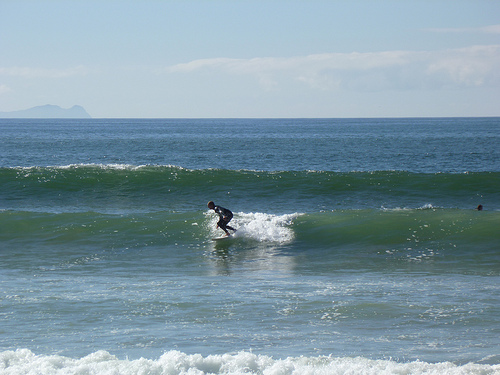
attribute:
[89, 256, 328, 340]
water — blue, clear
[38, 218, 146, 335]
water — clear, blue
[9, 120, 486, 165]
ocean — blue, deep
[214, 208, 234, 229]
suit — wet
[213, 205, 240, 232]
suit — wet, surfer's, black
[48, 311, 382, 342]
water — cream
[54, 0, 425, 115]
sky — blue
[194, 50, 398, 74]
clouds — puffy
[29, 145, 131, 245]
waves — multiple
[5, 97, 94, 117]
mountain — in the distance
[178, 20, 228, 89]
part — of the sky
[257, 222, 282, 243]
part — of a water splash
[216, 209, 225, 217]
part — of a swimming costume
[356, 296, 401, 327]
part — of a water surface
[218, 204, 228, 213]
back — of a man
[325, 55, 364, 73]
part — of a cloud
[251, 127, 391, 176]
part — of a water body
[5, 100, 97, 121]
mountains — on the horizon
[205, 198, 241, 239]
surfer — fast adventures, catching a wave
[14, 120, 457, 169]
ocean — dark blue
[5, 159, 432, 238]
wave — behind the surfer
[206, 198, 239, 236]
surfer — wearing a wetsuit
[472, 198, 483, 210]
surfer — waiting behind a wave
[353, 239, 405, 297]
water — blue, clear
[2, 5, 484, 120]
sky — blue